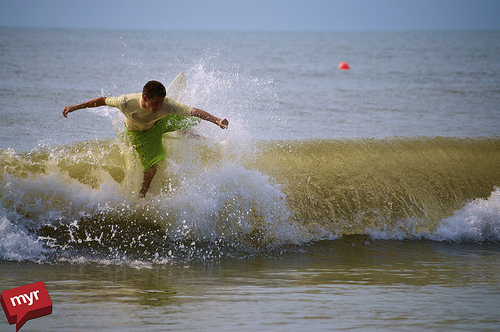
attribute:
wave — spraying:
[29, 135, 498, 237]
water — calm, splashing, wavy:
[4, 26, 497, 330]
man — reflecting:
[58, 80, 238, 210]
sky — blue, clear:
[3, 1, 496, 39]